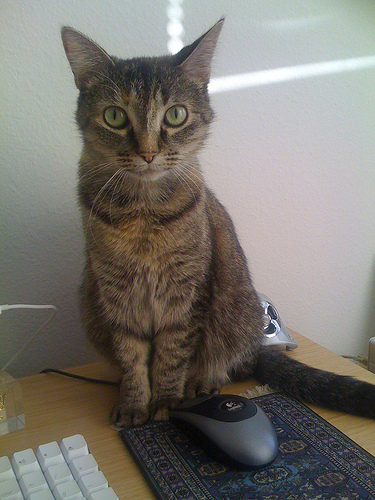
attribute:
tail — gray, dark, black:
[256, 345, 374, 420]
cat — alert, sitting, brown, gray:
[61, 14, 375, 429]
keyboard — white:
[0, 434, 121, 500]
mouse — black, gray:
[168, 393, 280, 472]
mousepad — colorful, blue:
[109, 382, 375, 499]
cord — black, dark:
[38, 368, 120, 388]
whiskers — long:
[77, 156, 209, 246]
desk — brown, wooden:
[0, 325, 375, 500]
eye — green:
[166, 103, 188, 126]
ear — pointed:
[174, 16, 226, 86]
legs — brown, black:
[85, 256, 208, 396]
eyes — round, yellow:
[102, 104, 188, 126]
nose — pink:
[136, 147, 161, 163]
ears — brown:
[61, 15, 227, 91]